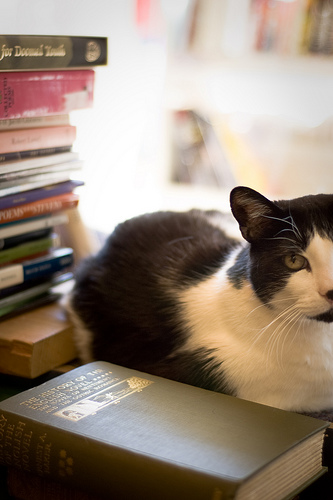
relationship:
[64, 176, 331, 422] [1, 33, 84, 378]
cat besides books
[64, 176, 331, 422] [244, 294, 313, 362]
cat has whiskers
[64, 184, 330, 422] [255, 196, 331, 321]
cat has face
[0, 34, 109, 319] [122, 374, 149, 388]
book has gold leaf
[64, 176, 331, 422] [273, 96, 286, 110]
cat on ground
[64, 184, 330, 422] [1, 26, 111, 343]
cat next books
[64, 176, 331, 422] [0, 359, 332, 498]
cat next book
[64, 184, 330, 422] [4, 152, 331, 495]
cat face forward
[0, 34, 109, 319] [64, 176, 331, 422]
book front cat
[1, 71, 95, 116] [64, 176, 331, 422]
book front cat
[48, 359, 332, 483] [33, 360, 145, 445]
book has title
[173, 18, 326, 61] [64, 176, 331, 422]
shelf behind cat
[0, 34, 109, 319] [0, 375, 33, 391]
book on shelf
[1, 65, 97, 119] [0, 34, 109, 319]
red book on book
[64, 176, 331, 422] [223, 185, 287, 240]
cat has ear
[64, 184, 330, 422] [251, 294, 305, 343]
cat has whiskers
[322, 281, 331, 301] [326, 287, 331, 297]
nose has tip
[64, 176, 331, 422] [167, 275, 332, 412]
cat has white chest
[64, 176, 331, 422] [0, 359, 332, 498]
cat behind book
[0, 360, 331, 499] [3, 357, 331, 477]
book has cover